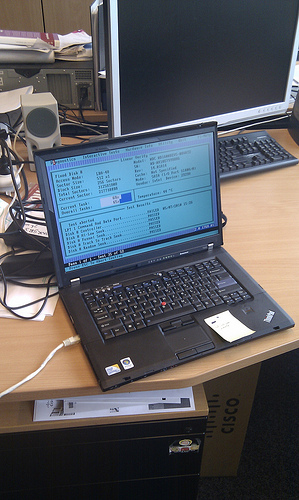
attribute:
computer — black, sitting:
[40, 156, 232, 344]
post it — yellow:
[191, 302, 250, 357]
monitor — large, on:
[97, 5, 297, 100]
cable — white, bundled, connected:
[11, 332, 92, 387]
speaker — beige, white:
[25, 73, 109, 132]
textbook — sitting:
[10, 30, 57, 58]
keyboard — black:
[113, 277, 230, 327]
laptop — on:
[72, 185, 263, 298]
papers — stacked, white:
[12, 34, 111, 70]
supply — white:
[22, 330, 62, 376]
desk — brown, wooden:
[23, 327, 287, 411]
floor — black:
[131, 462, 288, 497]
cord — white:
[1, 359, 65, 398]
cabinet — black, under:
[73, 432, 221, 489]